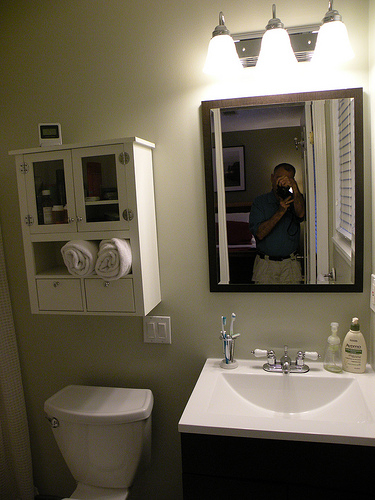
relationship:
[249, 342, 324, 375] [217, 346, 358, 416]
faucet on sink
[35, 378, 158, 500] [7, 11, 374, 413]
toilet in bathroom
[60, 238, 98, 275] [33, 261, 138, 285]
towel on shelf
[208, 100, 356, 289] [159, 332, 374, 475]
mirror above sink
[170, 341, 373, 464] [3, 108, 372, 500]
sink in bathroom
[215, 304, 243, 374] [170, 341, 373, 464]
toothbrushes by sink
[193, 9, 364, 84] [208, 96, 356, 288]
lamps above mirror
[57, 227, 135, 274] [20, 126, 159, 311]
towel on a shelf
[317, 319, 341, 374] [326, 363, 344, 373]
bottle of soap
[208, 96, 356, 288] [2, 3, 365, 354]
mirror hung on wall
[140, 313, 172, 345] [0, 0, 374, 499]
light switch on wall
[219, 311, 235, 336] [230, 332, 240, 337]
tooth brushes and a razor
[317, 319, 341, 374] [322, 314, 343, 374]
bottle with soap